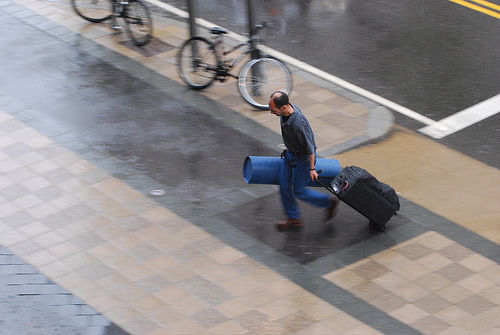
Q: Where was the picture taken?
A: It was taken at the sidewalk.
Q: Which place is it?
A: It is a sidewalk.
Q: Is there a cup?
A: No, there are no cups.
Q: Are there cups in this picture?
A: No, there are no cups.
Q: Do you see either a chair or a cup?
A: No, there are no cups or chairs.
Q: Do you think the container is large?
A: Yes, the container is large.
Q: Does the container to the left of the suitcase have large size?
A: Yes, the container is large.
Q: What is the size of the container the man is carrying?
A: The container is large.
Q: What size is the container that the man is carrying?
A: The container is large.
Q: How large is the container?
A: The container is large.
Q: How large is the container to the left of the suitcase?
A: The container is large.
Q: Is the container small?
A: No, the container is large.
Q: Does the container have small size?
A: No, the container is large.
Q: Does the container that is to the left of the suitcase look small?
A: No, the container is large.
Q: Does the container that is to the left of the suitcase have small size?
A: No, the container is large.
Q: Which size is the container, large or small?
A: The container is large.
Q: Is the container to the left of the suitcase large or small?
A: The container is large.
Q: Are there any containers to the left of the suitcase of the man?
A: Yes, there is a container to the left of the suitcase.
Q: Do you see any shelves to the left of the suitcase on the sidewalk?
A: No, there is a container to the left of the suitcase.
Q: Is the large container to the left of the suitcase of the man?
A: Yes, the container is to the left of the suitcase.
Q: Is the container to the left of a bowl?
A: No, the container is to the left of the suitcase.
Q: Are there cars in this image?
A: No, there are no cars.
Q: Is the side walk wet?
A: Yes, the side walk is wet.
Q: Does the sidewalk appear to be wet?
A: Yes, the sidewalk is wet.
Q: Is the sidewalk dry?
A: No, the sidewalk is wet.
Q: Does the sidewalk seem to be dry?
A: No, the sidewalk is wet.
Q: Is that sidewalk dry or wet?
A: The sidewalk is wet.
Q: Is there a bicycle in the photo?
A: Yes, there is a bicycle.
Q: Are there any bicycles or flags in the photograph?
A: Yes, there is a bicycle.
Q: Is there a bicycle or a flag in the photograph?
A: Yes, there is a bicycle.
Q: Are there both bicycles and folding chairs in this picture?
A: No, there is a bicycle but no folding chairs.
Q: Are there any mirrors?
A: No, there are no mirrors.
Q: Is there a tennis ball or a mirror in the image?
A: No, there are no mirrors or tennis balls.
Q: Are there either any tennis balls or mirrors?
A: No, there are no mirrors or tennis balls.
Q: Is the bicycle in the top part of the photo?
A: Yes, the bicycle is in the top of the image.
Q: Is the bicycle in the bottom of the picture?
A: No, the bicycle is in the top of the image.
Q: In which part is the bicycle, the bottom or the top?
A: The bicycle is in the top of the image.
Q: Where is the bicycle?
A: The bicycle is on the side walk.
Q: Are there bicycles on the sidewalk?
A: Yes, there is a bicycle on the sidewalk.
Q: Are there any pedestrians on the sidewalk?
A: No, there is a bicycle on the sidewalk.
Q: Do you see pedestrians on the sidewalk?
A: No, there is a bicycle on the sidewalk.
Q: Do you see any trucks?
A: No, there are no trucks.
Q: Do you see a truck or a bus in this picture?
A: No, there are no trucks or buses.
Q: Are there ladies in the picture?
A: No, there are no ladies.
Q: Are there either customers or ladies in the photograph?
A: No, there are no ladies or customers.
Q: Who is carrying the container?
A: The man is carrying the container.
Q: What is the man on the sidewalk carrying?
A: The man is carrying a container.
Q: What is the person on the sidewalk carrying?
A: The man is carrying a container.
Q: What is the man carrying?
A: The man is carrying a container.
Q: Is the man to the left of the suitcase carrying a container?
A: Yes, the man is carrying a container.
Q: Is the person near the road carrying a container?
A: Yes, the man is carrying a container.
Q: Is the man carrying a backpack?
A: No, the man is carrying a container.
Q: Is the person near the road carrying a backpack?
A: No, the man is carrying a container.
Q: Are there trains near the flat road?
A: No, there is a man near the road.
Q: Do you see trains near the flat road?
A: No, there is a man near the road.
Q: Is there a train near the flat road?
A: No, there is a man near the road.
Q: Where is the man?
A: The man is on the sidewalk.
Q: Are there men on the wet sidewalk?
A: Yes, there is a man on the sidewalk.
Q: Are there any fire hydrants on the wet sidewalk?
A: No, there is a man on the sidewalk.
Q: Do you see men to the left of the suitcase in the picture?
A: Yes, there is a man to the left of the suitcase.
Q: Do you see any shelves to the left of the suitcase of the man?
A: No, there is a man to the left of the suitcase.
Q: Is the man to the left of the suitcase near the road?
A: Yes, the man is to the left of the suitcase.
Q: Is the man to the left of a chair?
A: No, the man is to the left of the suitcase.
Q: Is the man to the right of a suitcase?
A: No, the man is to the left of a suitcase.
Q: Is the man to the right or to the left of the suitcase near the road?
A: The man is to the left of the suitcase.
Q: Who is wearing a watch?
A: The man is wearing a watch.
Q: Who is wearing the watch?
A: The man is wearing a watch.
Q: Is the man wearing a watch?
A: Yes, the man is wearing a watch.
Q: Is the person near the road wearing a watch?
A: Yes, the man is wearing a watch.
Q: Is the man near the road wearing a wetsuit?
A: No, the man is wearing a watch.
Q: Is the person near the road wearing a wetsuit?
A: No, the man is wearing a watch.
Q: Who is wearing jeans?
A: The man is wearing jeans.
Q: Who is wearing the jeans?
A: The man is wearing jeans.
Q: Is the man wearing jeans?
A: Yes, the man is wearing jeans.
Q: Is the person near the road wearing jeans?
A: Yes, the man is wearing jeans.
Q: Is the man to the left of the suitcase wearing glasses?
A: No, the man is wearing jeans.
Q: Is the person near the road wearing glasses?
A: No, the man is wearing jeans.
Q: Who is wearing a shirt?
A: The man is wearing a shirt.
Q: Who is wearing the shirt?
A: The man is wearing a shirt.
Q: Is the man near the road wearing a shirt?
A: Yes, the man is wearing a shirt.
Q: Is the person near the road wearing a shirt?
A: Yes, the man is wearing a shirt.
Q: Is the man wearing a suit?
A: No, the man is wearing a shirt.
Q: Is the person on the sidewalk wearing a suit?
A: No, the man is wearing a shirt.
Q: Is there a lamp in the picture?
A: No, there are no lamps.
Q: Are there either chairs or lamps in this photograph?
A: No, there are no lamps or chairs.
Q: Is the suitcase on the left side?
A: No, the suitcase is on the right of the image.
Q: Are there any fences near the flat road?
A: No, there is a suitcase near the road.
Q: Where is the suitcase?
A: The suitcase is on the side walk.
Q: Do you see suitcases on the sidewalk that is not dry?
A: Yes, there is a suitcase on the side walk.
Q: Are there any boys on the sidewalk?
A: No, there is a suitcase on the sidewalk.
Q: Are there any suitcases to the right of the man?
A: Yes, there is a suitcase to the right of the man.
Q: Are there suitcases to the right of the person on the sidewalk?
A: Yes, there is a suitcase to the right of the man.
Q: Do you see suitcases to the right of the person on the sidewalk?
A: Yes, there is a suitcase to the right of the man.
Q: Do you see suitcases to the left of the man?
A: No, the suitcase is to the right of the man.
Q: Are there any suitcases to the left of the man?
A: No, the suitcase is to the right of the man.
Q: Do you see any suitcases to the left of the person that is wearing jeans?
A: No, the suitcase is to the right of the man.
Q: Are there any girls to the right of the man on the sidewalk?
A: No, there is a suitcase to the right of the man.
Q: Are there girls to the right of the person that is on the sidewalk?
A: No, there is a suitcase to the right of the man.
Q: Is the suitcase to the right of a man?
A: Yes, the suitcase is to the right of a man.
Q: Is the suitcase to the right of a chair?
A: No, the suitcase is to the right of a man.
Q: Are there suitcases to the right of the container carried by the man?
A: Yes, there is a suitcase to the right of the container.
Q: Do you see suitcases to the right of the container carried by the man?
A: Yes, there is a suitcase to the right of the container.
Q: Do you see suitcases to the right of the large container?
A: Yes, there is a suitcase to the right of the container.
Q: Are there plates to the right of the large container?
A: No, there is a suitcase to the right of the container.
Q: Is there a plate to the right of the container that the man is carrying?
A: No, there is a suitcase to the right of the container.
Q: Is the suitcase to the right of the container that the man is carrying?
A: Yes, the suitcase is to the right of the container.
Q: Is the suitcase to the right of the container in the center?
A: Yes, the suitcase is to the right of the container.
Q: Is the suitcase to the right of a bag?
A: No, the suitcase is to the right of the container.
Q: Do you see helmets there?
A: No, there are no helmets.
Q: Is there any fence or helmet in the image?
A: No, there are no helmets or fences.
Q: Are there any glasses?
A: No, there are no glasses.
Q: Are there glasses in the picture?
A: No, there are no glasses.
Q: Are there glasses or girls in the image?
A: No, there are no glasses or girls.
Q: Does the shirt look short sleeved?
A: Yes, the shirt is short sleeved.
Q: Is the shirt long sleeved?
A: No, the shirt is short sleeved.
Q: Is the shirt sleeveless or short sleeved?
A: The shirt is short sleeved.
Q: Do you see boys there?
A: No, there are no boys.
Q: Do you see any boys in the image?
A: No, there are no boys.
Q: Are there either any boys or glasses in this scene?
A: No, there are no boys or glasses.